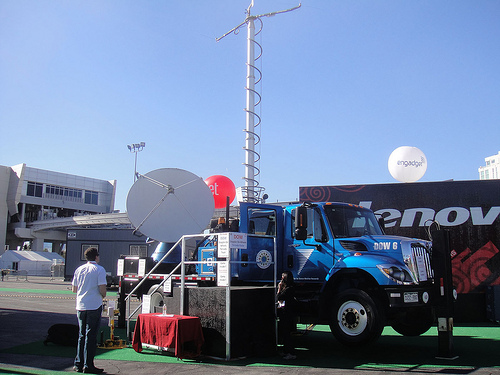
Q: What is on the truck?
A: A satelitte dish.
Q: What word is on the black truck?
A: Lenova.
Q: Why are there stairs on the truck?
A: To climb.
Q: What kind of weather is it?
A: Clear.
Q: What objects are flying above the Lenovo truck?
A: Balloons.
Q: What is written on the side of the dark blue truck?
A: Lenovo.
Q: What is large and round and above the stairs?
A: The satellite.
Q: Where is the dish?
A: Above the stairs.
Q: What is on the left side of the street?
A: A building.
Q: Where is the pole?
A: On top of the truck.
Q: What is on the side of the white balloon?
A: Letters.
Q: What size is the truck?
A: Large.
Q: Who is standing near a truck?
A: A man.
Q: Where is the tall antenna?
A: On the truck.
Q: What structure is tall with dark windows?
A: The building.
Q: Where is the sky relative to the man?
A: Above the man.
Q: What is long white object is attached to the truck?
A: An antenna.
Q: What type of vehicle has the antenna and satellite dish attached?
A: A truck.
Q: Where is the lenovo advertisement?
A: Behind the truck.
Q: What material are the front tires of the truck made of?
A: Rubber.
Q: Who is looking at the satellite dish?
A: The man.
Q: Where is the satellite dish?
A: On the truck.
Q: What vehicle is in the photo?
A: A truck.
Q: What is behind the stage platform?
A: A truck.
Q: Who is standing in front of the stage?
A: A man.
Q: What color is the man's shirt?
A: White.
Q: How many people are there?
A: Two.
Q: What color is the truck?
A: Blue.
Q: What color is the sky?
A: Blue.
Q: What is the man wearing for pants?
A: Jeans.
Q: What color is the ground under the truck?
A: Green.